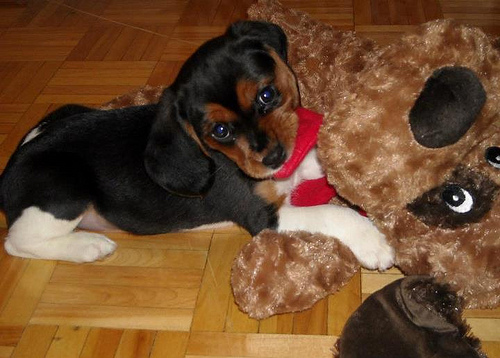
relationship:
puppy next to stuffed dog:
[0, 19, 395, 271] [228, 1, 499, 358]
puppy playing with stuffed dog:
[0, 19, 395, 271] [228, 1, 499, 358]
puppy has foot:
[0, 19, 395, 271] [4, 207, 118, 264]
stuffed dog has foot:
[228, 1, 499, 358] [98, 82, 170, 108]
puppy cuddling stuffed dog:
[0, 19, 395, 271] [228, 1, 499, 358]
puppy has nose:
[0, 19, 395, 271] [261, 148, 284, 165]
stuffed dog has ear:
[228, 1, 499, 358] [334, 276, 486, 356]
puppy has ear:
[0, 19, 395, 271] [143, 85, 218, 199]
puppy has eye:
[0, 19, 395, 271] [256, 84, 278, 105]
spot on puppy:
[21, 123, 46, 146] [0, 19, 395, 271]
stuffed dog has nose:
[228, 1, 499, 358] [410, 64, 485, 149]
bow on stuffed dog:
[271, 98, 339, 207] [228, 1, 499, 358]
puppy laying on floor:
[0, 19, 395, 271] [2, 1, 251, 166]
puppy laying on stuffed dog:
[0, 19, 395, 271] [228, 1, 499, 358]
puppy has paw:
[0, 19, 395, 271] [286, 203, 397, 273]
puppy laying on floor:
[0, 19, 395, 271] [3, 227, 399, 357]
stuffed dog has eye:
[228, 1, 499, 358] [441, 185, 472, 214]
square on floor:
[67, 23, 176, 61] [2, 1, 251, 166]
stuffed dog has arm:
[228, 1, 499, 358] [229, 228, 362, 321]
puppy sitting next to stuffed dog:
[0, 19, 395, 271] [228, 1, 499, 358]